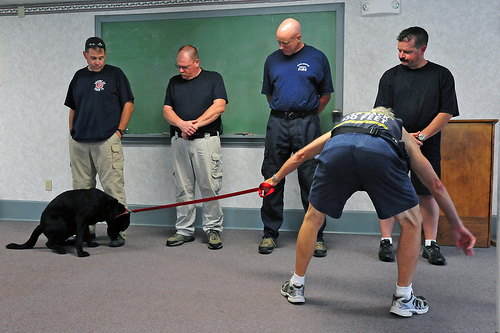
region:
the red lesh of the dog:
[117, 180, 273, 232]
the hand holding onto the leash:
[257, 173, 282, 203]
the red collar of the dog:
[109, 201, 130, 223]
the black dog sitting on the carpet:
[7, 190, 131, 261]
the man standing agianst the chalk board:
[160, 49, 225, 256]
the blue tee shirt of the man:
[261, 43, 329, 118]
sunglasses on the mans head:
[83, 38, 107, 54]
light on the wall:
[357, 0, 407, 20]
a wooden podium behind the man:
[440, 118, 498, 233]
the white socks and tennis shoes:
[271, 269, 431, 324]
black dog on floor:
[0, 189, 142, 271]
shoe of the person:
[270, 276, 302, 304]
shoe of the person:
[375, 291, 433, 321]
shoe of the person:
[156, 228, 187, 246]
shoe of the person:
[206, 229, 223, 249]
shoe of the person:
[255, 232, 280, 256]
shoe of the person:
[316, 243, 328, 258]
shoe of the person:
[373, 244, 395, 267]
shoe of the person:
[426, 247, 443, 271]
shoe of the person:
[111, 234, 133, 253]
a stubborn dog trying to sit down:
[6, 180, 134, 259]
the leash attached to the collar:
[132, 179, 270, 213]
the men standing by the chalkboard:
[59, 18, 319, 253]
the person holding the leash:
[266, 102, 486, 331]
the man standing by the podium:
[373, 33, 464, 270]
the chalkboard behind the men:
[95, 7, 350, 147]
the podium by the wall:
[436, 120, 491, 243]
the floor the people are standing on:
[6, 219, 496, 330]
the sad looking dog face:
[106, 207, 131, 241]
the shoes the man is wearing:
[280, 273, 435, 322]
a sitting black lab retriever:
[6, 188, 129, 257]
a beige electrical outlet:
[44, 178, 50, 192]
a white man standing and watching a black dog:
[6, 37, 129, 256]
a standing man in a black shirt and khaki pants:
[164, 44, 226, 249]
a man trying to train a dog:
[6, 106, 476, 317]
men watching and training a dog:
[6, 18, 476, 316]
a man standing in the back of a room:
[258, 17, 333, 258]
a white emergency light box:
[360, 0, 402, 14]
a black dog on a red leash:
[6, 183, 275, 255]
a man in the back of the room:
[373, 27, 458, 266]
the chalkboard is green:
[218, 35, 248, 68]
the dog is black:
[69, 197, 95, 224]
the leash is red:
[141, 202, 193, 212]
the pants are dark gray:
[94, 146, 118, 173]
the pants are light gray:
[176, 144, 194, 174]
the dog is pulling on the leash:
[108, 196, 133, 248]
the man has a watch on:
[115, 121, 131, 141]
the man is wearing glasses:
[169, 55, 196, 75]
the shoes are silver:
[277, 268, 311, 304]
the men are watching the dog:
[81, 24, 438, 92]